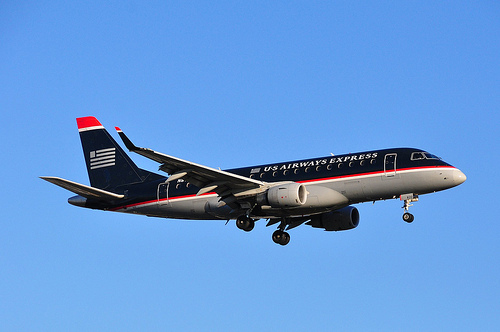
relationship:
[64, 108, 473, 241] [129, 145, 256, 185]
plane has wing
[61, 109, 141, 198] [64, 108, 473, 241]
tail of plane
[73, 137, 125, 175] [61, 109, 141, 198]
flag on tail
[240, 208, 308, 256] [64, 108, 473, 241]
tires on bottom of plane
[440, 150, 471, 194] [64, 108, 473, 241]
nose of plane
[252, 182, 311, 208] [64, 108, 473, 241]
propeller on plane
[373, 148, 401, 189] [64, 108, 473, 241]
door of plane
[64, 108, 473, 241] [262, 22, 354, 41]
plane in sky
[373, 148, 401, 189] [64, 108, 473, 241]
door on plane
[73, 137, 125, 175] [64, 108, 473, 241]
flag on plane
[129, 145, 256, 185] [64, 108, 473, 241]
wing of plane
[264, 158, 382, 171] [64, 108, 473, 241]
white words on plane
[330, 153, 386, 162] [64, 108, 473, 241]
express on plane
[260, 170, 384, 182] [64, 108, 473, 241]
windows on plane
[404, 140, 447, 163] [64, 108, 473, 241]
windows on front of plane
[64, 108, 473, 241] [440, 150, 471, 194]
plane has nose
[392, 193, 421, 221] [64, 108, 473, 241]
wheel under plane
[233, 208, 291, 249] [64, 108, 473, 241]
hind wheel under plane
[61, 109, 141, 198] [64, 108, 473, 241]
tail on plane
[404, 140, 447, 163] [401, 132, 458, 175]
windows of cockpit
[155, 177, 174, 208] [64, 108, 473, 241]
back door of plane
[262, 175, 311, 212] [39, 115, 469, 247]
propeller on plane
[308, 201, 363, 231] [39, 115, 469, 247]
propeller on plane